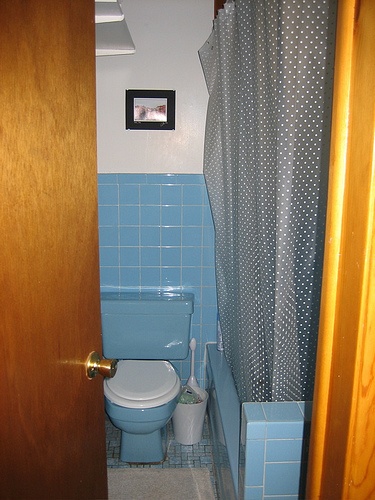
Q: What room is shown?
A: It is a bathroom.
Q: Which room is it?
A: It is a bathroom.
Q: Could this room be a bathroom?
A: Yes, it is a bathroom.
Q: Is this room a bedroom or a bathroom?
A: It is a bathroom.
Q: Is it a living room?
A: No, it is a bathroom.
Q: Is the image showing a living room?
A: No, the picture is showing a bathroom.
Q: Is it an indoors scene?
A: Yes, it is indoors.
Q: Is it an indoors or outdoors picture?
A: It is indoors.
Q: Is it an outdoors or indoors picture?
A: It is indoors.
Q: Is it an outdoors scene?
A: No, it is indoors.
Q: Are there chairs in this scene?
A: No, there are no chairs.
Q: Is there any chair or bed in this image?
A: No, there are no chairs or beds.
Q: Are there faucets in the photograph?
A: No, there are no faucets.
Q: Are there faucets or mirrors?
A: No, there are no faucets or mirrors.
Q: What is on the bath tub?
A: The tiles are on the bath tub.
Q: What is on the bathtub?
A: The tiles are on the bath tub.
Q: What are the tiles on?
A: The tiles are on the bath tub.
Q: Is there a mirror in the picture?
A: No, there are no mirrors.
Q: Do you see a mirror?
A: No, there are no mirrors.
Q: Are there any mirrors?
A: No, there are no mirrors.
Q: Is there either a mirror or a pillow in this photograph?
A: No, there are no mirrors or pillows.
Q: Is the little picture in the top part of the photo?
A: Yes, the picture is in the top of the image.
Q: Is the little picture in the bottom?
A: No, the picture is in the top of the image.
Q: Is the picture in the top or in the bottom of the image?
A: The picture is in the top of the image.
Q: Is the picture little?
A: Yes, the picture is little.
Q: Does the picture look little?
A: Yes, the picture is little.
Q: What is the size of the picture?
A: The picture is little.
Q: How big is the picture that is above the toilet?
A: The picture is little.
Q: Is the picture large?
A: No, the picture is little.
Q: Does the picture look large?
A: No, the picture is little.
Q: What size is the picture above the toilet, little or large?
A: The picture is little.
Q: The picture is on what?
A: The picture is on the wall.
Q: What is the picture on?
A: The picture is on the wall.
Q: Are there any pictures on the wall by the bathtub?
A: Yes, there is a picture on the wall.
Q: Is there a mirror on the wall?
A: No, there is a picture on the wall.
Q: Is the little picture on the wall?
A: Yes, the picture is on the wall.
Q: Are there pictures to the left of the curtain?
A: Yes, there is a picture to the left of the curtain.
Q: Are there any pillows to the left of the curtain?
A: No, there is a picture to the left of the curtain.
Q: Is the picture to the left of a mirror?
A: No, the picture is to the left of the curtain.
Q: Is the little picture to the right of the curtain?
A: No, the picture is to the left of the curtain.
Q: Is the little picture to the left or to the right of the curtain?
A: The picture is to the left of the curtain.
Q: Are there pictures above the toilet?
A: Yes, there is a picture above the toilet.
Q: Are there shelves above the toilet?
A: No, there is a picture above the toilet.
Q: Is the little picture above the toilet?
A: Yes, the picture is above the toilet.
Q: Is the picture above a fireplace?
A: No, the picture is above the toilet.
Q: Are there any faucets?
A: No, there are no faucets.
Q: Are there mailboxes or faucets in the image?
A: No, there are no faucets or mailboxes.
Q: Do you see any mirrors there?
A: No, there are no mirrors.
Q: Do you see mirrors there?
A: No, there are no mirrors.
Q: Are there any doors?
A: Yes, there is a door.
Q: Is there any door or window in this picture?
A: Yes, there is a door.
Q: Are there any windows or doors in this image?
A: Yes, there is a door.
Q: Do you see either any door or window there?
A: Yes, there is a door.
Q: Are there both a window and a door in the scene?
A: No, there is a door but no windows.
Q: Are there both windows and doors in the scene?
A: No, there is a door but no windows.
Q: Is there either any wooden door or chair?
A: Yes, there is a wood door.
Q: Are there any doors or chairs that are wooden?
A: Yes, the door is wooden.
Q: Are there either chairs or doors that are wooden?
A: Yes, the door is wooden.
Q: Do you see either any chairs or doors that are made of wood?
A: Yes, the door is made of wood.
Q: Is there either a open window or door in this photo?
A: Yes, there is an open door.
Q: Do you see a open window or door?
A: Yes, there is an open door.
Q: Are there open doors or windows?
A: Yes, there is an open door.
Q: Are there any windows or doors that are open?
A: Yes, the door is open.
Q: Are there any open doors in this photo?
A: Yes, there is an open door.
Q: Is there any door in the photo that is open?
A: Yes, there is a door that is open.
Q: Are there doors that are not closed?
A: Yes, there is a open door.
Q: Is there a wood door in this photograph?
A: Yes, there is a wood door.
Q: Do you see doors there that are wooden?
A: Yes, there is a wood door.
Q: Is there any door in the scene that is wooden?
A: Yes, there is a door that is wooden.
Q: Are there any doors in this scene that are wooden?
A: Yes, there is a door that is wooden.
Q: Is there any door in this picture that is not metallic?
A: Yes, there is a wooden door.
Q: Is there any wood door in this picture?
A: Yes, there is a door that is made of wood.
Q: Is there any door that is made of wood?
A: Yes, there is a door that is made of wood.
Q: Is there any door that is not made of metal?
A: Yes, there is a door that is made of wood.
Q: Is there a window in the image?
A: No, there are no windows.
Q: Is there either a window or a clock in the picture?
A: No, there are no windows or clocks.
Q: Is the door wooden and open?
A: Yes, the door is wooden and open.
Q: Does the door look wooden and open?
A: Yes, the door is wooden and open.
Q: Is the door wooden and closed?
A: No, the door is wooden but open.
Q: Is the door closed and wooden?
A: No, the door is wooden but open.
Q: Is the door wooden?
A: Yes, the door is wooden.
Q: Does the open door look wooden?
A: Yes, the door is wooden.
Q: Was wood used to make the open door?
A: Yes, the door is made of wood.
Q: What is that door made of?
A: The door is made of wood.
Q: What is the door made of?
A: The door is made of wood.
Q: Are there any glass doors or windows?
A: No, there is a door but it is wooden.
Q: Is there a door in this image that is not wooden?
A: No, there is a door but it is wooden.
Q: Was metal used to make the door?
A: No, the door is made of wood.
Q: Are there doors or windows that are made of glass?
A: No, there is a door but it is made of wood.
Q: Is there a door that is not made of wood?
A: No, there is a door but it is made of wood.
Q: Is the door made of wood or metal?
A: The door is made of wood.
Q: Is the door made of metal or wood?
A: The door is made of wood.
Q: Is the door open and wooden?
A: Yes, the door is open and wooden.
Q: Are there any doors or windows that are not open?
A: No, there is a door but it is open.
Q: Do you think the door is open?
A: Yes, the door is open.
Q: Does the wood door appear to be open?
A: Yes, the door is open.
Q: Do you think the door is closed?
A: No, the door is open.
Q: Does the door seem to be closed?
A: No, the door is open.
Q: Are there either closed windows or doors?
A: No, there is a door but it is open.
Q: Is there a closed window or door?
A: No, there is a door but it is open.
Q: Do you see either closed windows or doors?
A: No, there is a door but it is open.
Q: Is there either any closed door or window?
A: No, there is a door but it is open.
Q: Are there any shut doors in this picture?
A: No, there is a door but it is open.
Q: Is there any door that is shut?
A: No, there is a door but it is open.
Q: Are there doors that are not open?
A: No, there is a door but it is open.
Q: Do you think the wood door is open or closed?
A: The door is open.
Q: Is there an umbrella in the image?
A: No, there are no umbrellas.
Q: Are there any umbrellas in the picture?
A: No, there are no umbrellas.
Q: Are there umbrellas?
A: No, there are no umbrellas.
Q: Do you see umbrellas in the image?
A: No, there are no umbrellas.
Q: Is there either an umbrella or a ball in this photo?
A: No, there are no umbrellas or balls.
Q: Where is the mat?
A: The mat is on the floor.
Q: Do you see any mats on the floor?
A: Yes, there is a mat on the floor.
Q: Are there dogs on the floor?
A: No, there is a mat on the floor.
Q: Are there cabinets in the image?
A: No, there are no cabinets.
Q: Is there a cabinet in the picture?
A: No, there are no cabinets.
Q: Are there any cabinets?
A: No, there are no cabinets.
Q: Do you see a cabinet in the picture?
A: No, there are no cabinets.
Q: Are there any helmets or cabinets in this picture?
A: No, there are no cabinets or helmets.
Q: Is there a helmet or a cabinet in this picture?
A: No, there are no cabinets or helmets.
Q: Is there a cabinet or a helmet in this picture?
A: No, there are no cabinets or helmets.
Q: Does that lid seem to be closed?
A: Yes, the lid is closed.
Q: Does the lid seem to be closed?
A: Yes, the lid is closed.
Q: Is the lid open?
A: No, the lid is closed.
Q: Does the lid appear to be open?
A: No, the lid is closed.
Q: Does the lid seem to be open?
A: No, the lid is closed.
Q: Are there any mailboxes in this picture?
A: No, there are no mailboxes.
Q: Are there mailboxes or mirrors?
A: No, there are no mailboxes or mirrors.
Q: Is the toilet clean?
A: Yes, the toilet is clean.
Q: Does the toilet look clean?
A: Yes, the toilet is clean.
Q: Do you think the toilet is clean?
A: Yes, the toilet is clean.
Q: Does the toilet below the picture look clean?
A: Yes, the toilet is clean.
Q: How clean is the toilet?
A: The toilet is clean.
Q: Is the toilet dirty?
A: No, the toilet is clean.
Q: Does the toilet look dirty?
A: No, the toilet is clean.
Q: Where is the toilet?
A: The toilet is in the bathroom.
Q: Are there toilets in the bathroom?
A: Yes, there is a toilet in the bathroom.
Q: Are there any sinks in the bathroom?
A: No, there is a toilet in the bathroom.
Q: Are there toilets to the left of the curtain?
A: Yes, there is a toilet to the left of the curtain.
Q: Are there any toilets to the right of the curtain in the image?
A: No, the toilet is to the left of the curtain.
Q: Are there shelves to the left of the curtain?
A: No, there is a toilet to the left of the curtain.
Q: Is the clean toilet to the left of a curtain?
A: Yes, the toilet is to the left of a curtain.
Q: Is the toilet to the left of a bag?
A: No, the toilet is to the left of a curtain.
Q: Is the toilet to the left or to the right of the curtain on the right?
A: The toilet is to the left of the curtain.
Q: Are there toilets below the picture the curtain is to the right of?
A: Yes, there is a toilet below the picture.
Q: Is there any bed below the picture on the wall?
A: No, there is a toilet below the picture.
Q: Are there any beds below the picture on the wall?
A: No, there is a toilet below the picture.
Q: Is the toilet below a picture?
A: Yes, the toilet is below a picture.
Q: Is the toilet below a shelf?
A: No, the toilet is below a picture.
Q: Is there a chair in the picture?
A: No, there are no chairs.